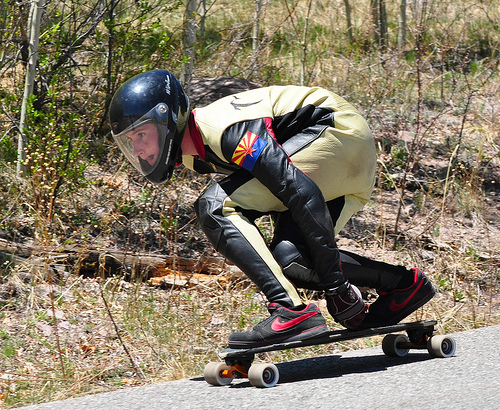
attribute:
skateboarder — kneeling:
[88, 56, 442, 350]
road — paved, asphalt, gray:
[336, 356, 496, 409]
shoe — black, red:
[222, 299, 334, 348]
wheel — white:
[249, 361, 279, 395]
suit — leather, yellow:
[196, 83, 390, 293]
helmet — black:
[104, 71, 188, 184]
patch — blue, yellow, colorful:
[233, 125, 270, 172]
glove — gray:
[316, 286, 376, 328]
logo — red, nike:
[269, 309, 328, 335]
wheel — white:
[199, 354, 233, 390]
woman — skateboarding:
[109, 68, 446, 346]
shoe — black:
[359, 269, 441, 323]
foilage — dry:
[13, 294, 203, 378]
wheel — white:
[426, 334, 459, 363]